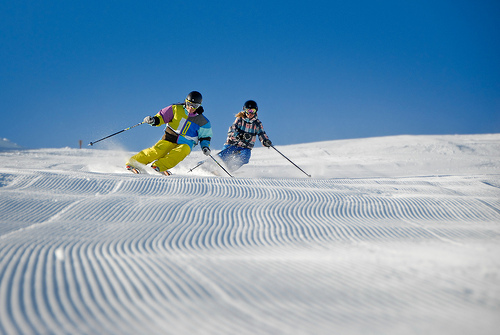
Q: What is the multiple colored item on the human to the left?
A: A jacket.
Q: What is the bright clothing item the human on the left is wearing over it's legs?
A: Pants.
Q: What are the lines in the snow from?
A: Skis.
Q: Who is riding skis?
A: The humans.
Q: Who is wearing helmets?
A: The humans.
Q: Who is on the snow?
A: The humans.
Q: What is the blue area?
A: The sky.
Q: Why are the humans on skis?
A: To move across the snow more quickly.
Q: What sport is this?
A: Skiing.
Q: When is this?
A: Daytime.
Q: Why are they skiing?
A: Fun.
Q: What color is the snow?
A: White.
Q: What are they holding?
A: Ski sticks.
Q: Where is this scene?
A: At a ski slope.